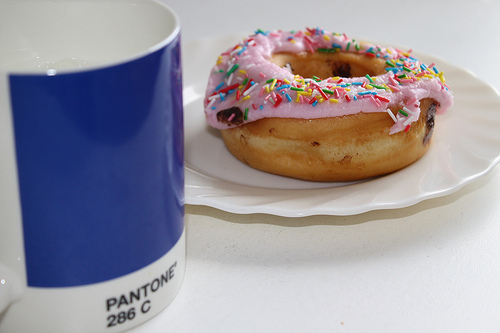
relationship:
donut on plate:
[202, 25, 454, 185] [178, 52, 499, 219]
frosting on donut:
[202, 26, 452, 137] [202, 25, 454, 185]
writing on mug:
[97, 259, 177, 329] [0, 0, 188, 329]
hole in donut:
[266, 45, 382, 81] [202, 25, 454, 185]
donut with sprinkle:
[202, 25, 454, 185] [241, 82, 259, 96]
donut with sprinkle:
[202, 25, 454, 185] [285, 91, 294, 101]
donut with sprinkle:
[202, 25, 454, 185] [297, 88, 313, 98]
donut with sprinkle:
[202, 25, 454, 185] [386, 105, 399, 124]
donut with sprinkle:
[202, 25, 454, 185] [240, 106, 250, 122]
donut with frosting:
[202, 25, 454, 185] [202, 26, 452, 137]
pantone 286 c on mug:
[97, 259, 177, 329] [0, 0, 188, 329]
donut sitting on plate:
[202, 25, 454, 185] [178, 52, 499, 219]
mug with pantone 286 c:
[0, 0, 188, 329] [97, 259, 177, 329]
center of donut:
[266, 45, 382, 81] [202, 25, 454, 185]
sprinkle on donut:
[285, 91, 294, 101] [202, 25, 454, 185]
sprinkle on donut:
[240, 106, 250, 122] [202, 25, 454, 185]